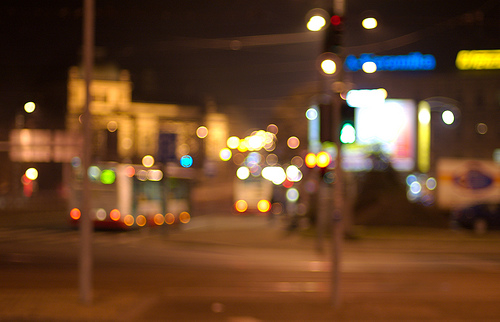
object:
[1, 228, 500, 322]
ground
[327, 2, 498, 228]
building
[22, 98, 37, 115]
light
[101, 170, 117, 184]
light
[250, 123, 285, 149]
light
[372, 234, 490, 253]
curb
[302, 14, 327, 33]
light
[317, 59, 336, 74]
light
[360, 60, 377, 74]
light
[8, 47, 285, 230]
building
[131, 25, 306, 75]
lines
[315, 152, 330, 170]
yellow light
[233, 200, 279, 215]
lights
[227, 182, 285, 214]
vehicle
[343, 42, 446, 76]
sign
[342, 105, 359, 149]
green light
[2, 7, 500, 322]
blurry scene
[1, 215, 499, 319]
road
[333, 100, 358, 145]
sign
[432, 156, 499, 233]
truck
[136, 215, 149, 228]
light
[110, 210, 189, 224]
light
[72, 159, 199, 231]
bus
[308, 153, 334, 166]
light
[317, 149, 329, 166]
light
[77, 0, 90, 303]
pole